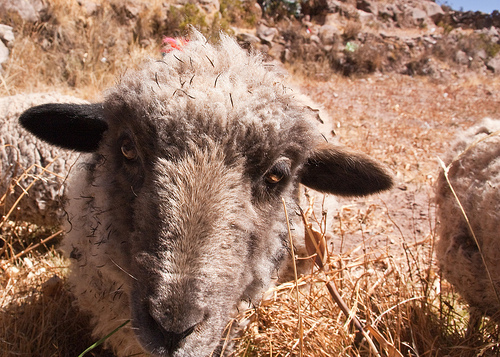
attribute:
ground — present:
[302, 75, 500, 270]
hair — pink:
[156, 34, 191, 51]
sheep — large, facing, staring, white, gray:
[19, 22, 395, 356]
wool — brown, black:
[147, 110, 274, 165]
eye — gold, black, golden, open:
[261, 155, 292, 184]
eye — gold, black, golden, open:
[118, 133, 139, 160]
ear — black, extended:
[300, 141, 394, 196]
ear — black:
[17, 101, 106, 151]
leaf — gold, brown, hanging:
[302, 224, 327, 265]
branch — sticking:
[295, 203, 381, 356]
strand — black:
[228, 91, 236, 108]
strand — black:
[205, 50, 218, 68]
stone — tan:
[256, 22, 279, 46]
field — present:
[2, 1, 500, 354]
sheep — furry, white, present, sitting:
[0, 92, 90, 226]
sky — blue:
[435, 1, 499, 12]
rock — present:
[2, 0, 50, 23]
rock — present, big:
[426, 1, 445, 25]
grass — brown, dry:
[233, 252, 499, 354]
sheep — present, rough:
[431, 113, 500, 316]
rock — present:
[124, 6, 141, 20]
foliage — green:
[344, 40, 354, 53]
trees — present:
[452, 11, 500, 28]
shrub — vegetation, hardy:
[340, 54, 378, 76]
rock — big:
[319, 12, 343, 44]